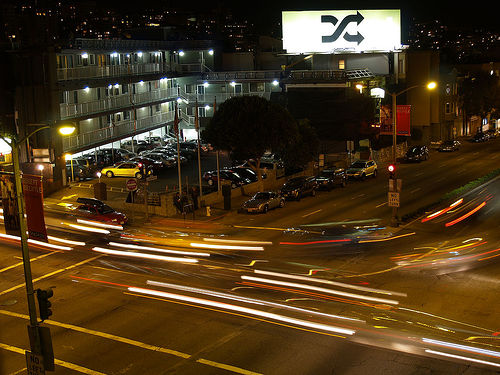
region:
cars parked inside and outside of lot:
[73, 83, 438, 235]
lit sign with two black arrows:
[290, 6, 395, 56]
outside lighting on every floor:
[50, 30, 270, 180]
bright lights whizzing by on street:
[70, 192, 485, 342]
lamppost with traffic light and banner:
[2, 115, 77, 327]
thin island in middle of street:
[350, 150, 492, 236]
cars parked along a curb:
[232, 120, 487, 216]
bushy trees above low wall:
[195, 55, 386, 220]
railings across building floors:
[57, 60, 192, 140]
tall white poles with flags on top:
[148, 85, 233, 225]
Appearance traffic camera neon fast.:
[28, 169, 482, 374]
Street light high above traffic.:
[14, 109, 99, 274]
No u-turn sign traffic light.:
[373, 150, 426, 236]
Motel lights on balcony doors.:
[50, 58, 175, 157]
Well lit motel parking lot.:
[84, 138, 197, 183]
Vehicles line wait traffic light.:
[239, 164, 378, 219]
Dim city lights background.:
[18, 1, 230, 36]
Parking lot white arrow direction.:
[47, 184, 92, 209]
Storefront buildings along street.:
[437, 106, 499, 148]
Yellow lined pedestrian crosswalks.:
[39, 248, 141, 370]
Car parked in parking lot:
[92, 151, 149, 188]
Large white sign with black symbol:
[252, 2, 423, 69]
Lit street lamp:
[40, 107, 85, 147]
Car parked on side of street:
[235, 178, 295, 228]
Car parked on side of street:
[272, 171, 318, 206]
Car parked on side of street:
[65, 188, 137, 240]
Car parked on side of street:
[344, 150, 379, 187]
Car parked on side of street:
[397, 133, 434, 170]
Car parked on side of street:
[439, 132, 464, 154]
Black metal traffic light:
[25, 277, 62, 336]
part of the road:
[339, 252, 434, 299]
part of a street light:
[51, 119, 83, 144]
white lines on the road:
[114, 337, 194, 366]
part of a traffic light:
[33, 290, 55, 322]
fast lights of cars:
[314, 262, 419, 332]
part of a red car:
[100, 204, 125, 222]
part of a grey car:
[246, 193, 270, 217]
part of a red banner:
[378, 103, 412, 139]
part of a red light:
[386, 157, 403, 179]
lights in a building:
[75, 43, 201, 113]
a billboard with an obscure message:
[271, 5, 408, 55]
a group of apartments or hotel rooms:
[45, 46, 221, 183]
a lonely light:
[414, 65, 454, 101]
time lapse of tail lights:
[419, 193, 487, 232]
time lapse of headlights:
[125, 278, 365, 339]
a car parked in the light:
[100, 157, 155, 182]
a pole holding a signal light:
[2, 103, 57, 373]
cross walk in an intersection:
[0, 236, 107, 295]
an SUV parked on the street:
[345, 156, 379, 183]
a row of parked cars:
[245, 156, 380, 223]